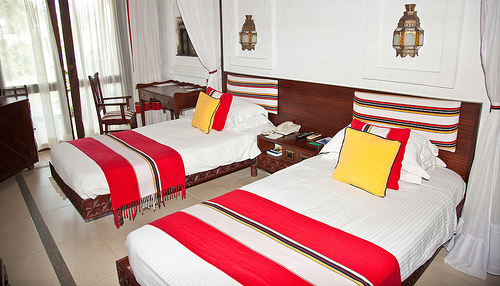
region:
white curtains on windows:
[5, 8, 78, 150]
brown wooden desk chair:
[85, 72, 142, 138]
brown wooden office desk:
[132, 71, 202, 134]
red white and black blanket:
[65, 118, 193, 219]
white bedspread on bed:
[180, 124, 227, 162]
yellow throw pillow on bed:
[334, 125, 404, 206]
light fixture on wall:
[375, 1, 447, 65]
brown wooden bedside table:
[255, 108, 337, 177]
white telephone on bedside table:
[272, 113, 302, 139]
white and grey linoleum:
[4, 188, 75, 283]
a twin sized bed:
[123, 119, 471, 281]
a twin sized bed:
[43, 95, 275, 212]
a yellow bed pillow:
[328, 123, 401, 197]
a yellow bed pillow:
[189, 89, 216, 131]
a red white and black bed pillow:
[344, 114, 409, 191]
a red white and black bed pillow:
[201, 82, 233, 132]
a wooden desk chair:
[85, 66, 137, 131]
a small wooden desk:
[132, 73, 200, 125]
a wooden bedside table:
[253, 118, 325, 175]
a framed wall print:
[168, 16, 200, 58]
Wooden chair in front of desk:
[87, 71, 142, 128]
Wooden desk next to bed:
[135, 75, 204, 120]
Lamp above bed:
[392, 2, 425, 59]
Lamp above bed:
[236, 10, 259, 52]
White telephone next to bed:
[272, 117, 301, 134]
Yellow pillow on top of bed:
[330, 125, 396, 195]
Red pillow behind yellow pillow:
[342, 115, 413, 190]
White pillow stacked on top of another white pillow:
[326, 117, 441, 171]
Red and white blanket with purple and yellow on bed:
[147, 179, 402, 284]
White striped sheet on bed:
[123, 155, 458, 284]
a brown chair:
[87, 75, 136, 130]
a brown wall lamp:
[387, 2, 428, 59]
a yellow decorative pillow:
[332, 126, 405, 201]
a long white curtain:
[442, 2, 499, 279]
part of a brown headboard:
[282, 82, 351, 133]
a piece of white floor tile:
[43, 205, 88, 240]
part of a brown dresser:
[1, 97, 43, 179]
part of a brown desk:
[135, 75, 205, 125]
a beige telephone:
[262, 117, 302, 134]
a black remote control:
[293, 127, 313, 142]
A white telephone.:
[270, 120, 302, 137]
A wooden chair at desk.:
[78, 70, 142, 133]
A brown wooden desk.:
[139, 75, 192, 117]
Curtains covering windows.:
[2, 5, 133, 137]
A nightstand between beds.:
[255, 125, 326, 173]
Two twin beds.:
[57, 94, 444, 281]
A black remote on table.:
[297, 128, 312, 138]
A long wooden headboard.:
[220, 74, 485, 162]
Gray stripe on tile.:
[9, 177, 81, 284]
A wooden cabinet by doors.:
[0, 95, 39, 179]